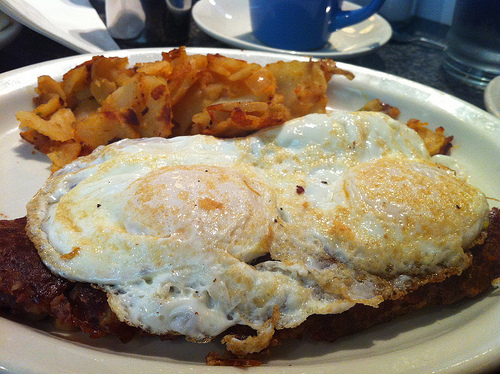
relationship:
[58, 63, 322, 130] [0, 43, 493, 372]
potatoes on plate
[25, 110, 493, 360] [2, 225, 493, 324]
egg on meat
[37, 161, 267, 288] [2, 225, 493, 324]
egg on meat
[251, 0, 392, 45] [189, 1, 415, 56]
mug on saucer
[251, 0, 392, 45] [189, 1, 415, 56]
mug with saucer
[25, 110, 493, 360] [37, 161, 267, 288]
egg with egg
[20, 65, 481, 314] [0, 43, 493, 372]
breakfast on plate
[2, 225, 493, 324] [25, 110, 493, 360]
meat under egg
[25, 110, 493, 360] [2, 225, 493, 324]
egg on top of meat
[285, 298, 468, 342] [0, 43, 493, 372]
shadow on plate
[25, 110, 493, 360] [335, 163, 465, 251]
egg has yolk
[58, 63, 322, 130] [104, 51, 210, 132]
potatoes in bunch